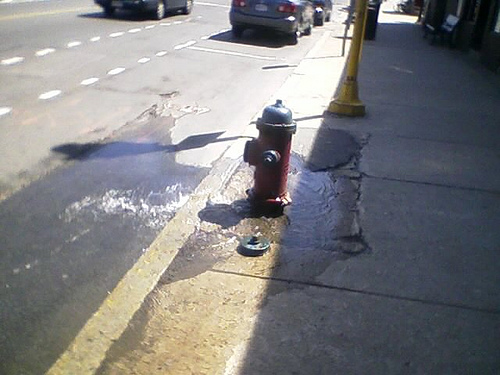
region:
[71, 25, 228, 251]
Water on road.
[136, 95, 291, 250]
Water running from the fire hydrant.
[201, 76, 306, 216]
Red fire hydrant with grey top.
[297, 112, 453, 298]
Broken sidewalk with water on.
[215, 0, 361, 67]
Grey car is parked.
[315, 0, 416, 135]
Yellow sign post.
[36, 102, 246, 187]
Shadow of a sign on the road.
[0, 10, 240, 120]
White traffic lines painted on the road.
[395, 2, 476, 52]
Bench tucked in the shadows on the sidewalk.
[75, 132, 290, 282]
Cap off of fire hydrant.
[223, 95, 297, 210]
red fire hydrant on the side of the street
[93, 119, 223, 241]
water leaking on the road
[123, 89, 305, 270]
water leaking from the fire hydrant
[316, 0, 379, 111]
yellow post on the side of the road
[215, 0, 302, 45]
car parked on side of the road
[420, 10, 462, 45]
bench on side walk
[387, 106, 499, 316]
paved side walk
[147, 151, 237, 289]
yellow painted curb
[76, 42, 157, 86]
white markings on the road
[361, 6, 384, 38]
garbage can on the side walk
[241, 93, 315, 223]
Red and gray fire hydrant.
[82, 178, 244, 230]
Water flowing from fire hydrant.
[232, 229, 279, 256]
Fire hydrant cap lying on sidewalk.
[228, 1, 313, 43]
Rear end of car.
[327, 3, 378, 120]
Yellow post on sidewalk.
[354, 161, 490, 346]
Indentations in sidewalk.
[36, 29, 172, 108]
White lines on road.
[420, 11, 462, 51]
Bench on sidewalk.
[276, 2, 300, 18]
A car's break lights.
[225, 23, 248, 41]
A car's rear tire.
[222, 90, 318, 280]
red fire hydrant in city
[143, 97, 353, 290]
open fire hydrant on street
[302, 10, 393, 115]
yellow post on sidewalk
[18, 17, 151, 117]
street at daytime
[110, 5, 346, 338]
city street during daytime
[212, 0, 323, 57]
parked gray car at curb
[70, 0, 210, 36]
car driving in street during day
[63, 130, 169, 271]
water in street from hydrant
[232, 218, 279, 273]
fire hydrant cap on ground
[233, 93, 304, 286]
red and silver fire hydrant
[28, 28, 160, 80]
broken white lines in street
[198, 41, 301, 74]
solid white lines in street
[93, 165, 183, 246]
puddle of water in street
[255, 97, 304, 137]
dark gray top of fire hydrant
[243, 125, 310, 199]
red base of fire hydrant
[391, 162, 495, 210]
lines on sidewalk pavement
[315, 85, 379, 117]
yellow base of tall object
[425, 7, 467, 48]
small blue and white chair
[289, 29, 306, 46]
black car wheels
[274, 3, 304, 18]
red rear lights on car